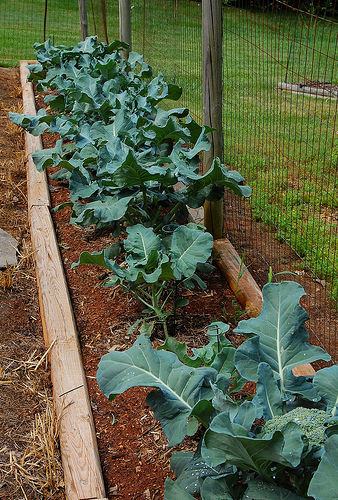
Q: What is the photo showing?
A: It is showing a garden.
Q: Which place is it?
A: It is a garden.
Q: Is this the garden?
A: Yes, it is the garden.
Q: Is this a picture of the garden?
A: Yes, it is showing the garden.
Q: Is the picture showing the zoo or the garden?
A: It is showing the garden.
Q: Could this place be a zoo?
A: No, it is a garden.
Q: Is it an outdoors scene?
A: Yes, it is outdoors.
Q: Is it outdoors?
A: Yes, it is outdoors.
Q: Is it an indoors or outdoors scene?
A: It is outdoors.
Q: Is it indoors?
A: No, it is outdoors.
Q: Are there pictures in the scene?
A: No, there are no pictures.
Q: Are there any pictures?
A: No, there are no pictures.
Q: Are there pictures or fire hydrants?
A: No, there are no pictures or fire hydrants.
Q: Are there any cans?
A: No, there are no cans.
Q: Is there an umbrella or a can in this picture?
A: No, there are no cans or umbrellas.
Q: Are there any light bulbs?
A: No, there are no light bulbs.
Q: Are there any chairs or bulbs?
A: No, there are no bulbs or chairs.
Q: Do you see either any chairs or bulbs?
A: No, there are no bulbs or chairs.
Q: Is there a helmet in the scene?
A: No, there are no helmets.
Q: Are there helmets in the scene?
A: No, there are no helmets.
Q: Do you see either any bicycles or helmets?
A: No, there are no helmets or bicycles.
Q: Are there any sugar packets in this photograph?
A: No, there are no sugar packets.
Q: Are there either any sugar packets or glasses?
A: No, there are no sugar packets or glasses.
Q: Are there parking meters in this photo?
A: No, there are no parking meters.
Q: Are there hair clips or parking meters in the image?
A: No, there are no parking meters or hair clips.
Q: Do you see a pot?
A: No, there are no pots.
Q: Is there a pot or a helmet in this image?
A: No, there are no pots or helmets.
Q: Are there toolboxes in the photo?
A: No, there are no toolboxes.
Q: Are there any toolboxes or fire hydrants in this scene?
A: No, there are no toolboxes or fire hydrants.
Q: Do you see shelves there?
A: No, there are no shelves.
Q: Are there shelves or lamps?
A: No, there are no shelves or lamps.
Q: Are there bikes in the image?
A: No, there are no bikes.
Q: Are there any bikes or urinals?
A: No, there are no bikes or urinals.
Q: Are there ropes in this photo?
A: No, there are no ropes.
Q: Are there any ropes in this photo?
A: No, there are no ropes.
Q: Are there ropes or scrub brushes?
A: No, there are no ropes or scrub brushes.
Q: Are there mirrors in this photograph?
A: No, there are no mirrors.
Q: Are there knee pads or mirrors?
A: No, there are no mirrors or knee pads.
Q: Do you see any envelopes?
A: No, there are no envelopes.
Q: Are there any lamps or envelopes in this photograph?
A: No, there are no envelopes or lamps.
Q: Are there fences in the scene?
A: Yes, there is a fence.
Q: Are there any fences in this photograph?
A: Yes, there is a fence.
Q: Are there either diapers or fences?
A: Yes, there is a fence.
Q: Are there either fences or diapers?
A: Yes, there is a fence.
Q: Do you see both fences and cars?
A: No, there is a fence but no cars.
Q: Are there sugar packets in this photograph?
A: No, there are no sugar packets.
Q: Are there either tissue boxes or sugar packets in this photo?
A: No, there are no sugar packets or tissue boxes.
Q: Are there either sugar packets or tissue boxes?
A: No, there are no sugar packets or tissue boxes.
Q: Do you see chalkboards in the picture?
A: No, there are no chalkboards.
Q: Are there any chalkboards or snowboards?
A: No, there are no chalkboards or snowboards.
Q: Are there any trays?
A: No, there are no trays.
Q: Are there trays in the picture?
A: No, there are no trays.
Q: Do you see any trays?
A: No, there are no trays.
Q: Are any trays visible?
A: No, there are no trays.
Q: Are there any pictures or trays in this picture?
A: No, there are no trays or pictures.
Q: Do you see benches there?
A: No, there are no benches.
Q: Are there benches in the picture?
A: No, there are no benches.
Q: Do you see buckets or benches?
A: No, there are no benches or buckets.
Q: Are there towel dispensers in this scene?
A: No, there are no towel dispensers.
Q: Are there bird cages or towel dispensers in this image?
A: No, there are no towel dispensers or bird cages.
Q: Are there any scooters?
A: No, there are no scooters.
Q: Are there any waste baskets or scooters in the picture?
A: No, there are no scooters or waste baskets.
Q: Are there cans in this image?
A: No, there are no cans.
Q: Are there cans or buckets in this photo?
A: No, there are no cans or buckets.